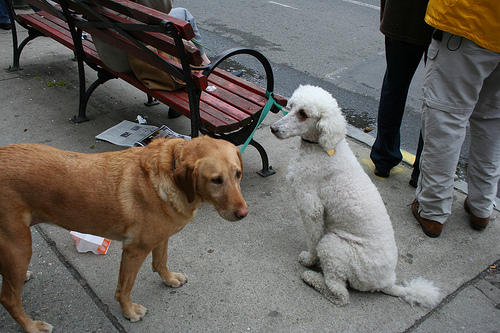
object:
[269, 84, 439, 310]
poodle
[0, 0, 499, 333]
sidewalk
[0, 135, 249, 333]
retriever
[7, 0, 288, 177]
bench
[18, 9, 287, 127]
seat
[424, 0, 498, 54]
windbreaker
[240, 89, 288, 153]
leash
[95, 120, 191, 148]
magazine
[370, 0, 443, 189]
person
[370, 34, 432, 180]
jeans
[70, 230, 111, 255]
paper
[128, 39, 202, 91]
bag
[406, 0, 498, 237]
man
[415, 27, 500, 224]
pants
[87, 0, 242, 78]
person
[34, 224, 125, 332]
crack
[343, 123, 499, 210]
curb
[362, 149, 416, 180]
streak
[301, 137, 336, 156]
collar